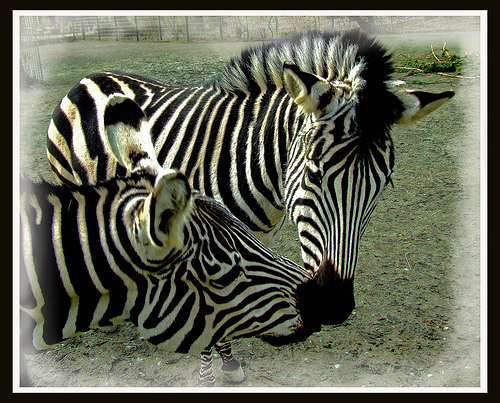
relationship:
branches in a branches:
[394, 41, 480, 79] [394, 41, 480, 79]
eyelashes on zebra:
[387, 170, 396, 186] [45, 25, 458, 343]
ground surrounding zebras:
[385, 180, 451, 359] [15, 22, 462, 381]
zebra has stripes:
[66, 51, 441, 311] [326, 194, 348, 232]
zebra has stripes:
[46, 29, 457, 387] [170, 117, 276, 161]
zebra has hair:
[46, 29, 457, 387] [214, 28, 397, 93]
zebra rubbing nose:
[46, 29, 457, 387] [317, 291, 355, 317]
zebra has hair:
[46, 29, 457, 387] [341, 51, 403, 154]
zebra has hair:
[46, 29, 457, 387] [251, 49, 379, 75]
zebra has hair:
[46, 29, 457, 387] [65, 167, 157, 191]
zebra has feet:
[46, 29, 457, 387] [197, 356, 275, 379]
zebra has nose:
[46, 29, 457, 387] [317, 291, 355, 317]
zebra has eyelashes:
[46, 29, 457, 387] [362, 137, 411, 197]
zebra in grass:
[46, 29, 457, 387] [389, 45, 469, 122]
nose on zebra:
[287, 256, 361, 356] [28, 40, 438, 327]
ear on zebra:
[132, 164, 231, 261] [46, 29, 457, 387]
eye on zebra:
[189, 258, 261, 296] [46, 29, 457, 387]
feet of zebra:
[221, 360, 245, 384] [46, 29, 457, 387]